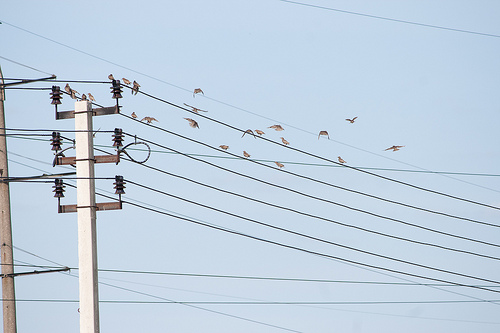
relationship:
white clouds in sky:
[399, 98, 495, 155] [0, 2, 499, 330]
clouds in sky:
[55, 0, 500, 278] [0, 2, 499, 330]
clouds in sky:
[58, 16, 498, 327] [203, 20, 445, 109]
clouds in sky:
[55, 0, 500, 278] [147, 12, 276, 96]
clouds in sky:
[55, 0, 500, 278] [124, 0, 499, 165]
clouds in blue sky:
[55, 0, 500, 278] [80, 1, 497, 132]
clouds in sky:
[55, 0, 500, 278] [4, 1, 499, 281]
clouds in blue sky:
[55, 0, 500, 278] [15, 5, 500, 158]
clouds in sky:
[55, 0, 500, 278] [212, 27, 433, 124]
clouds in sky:
[55, 0, 500, 278] [12, 11, 475, 331]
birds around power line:
[316, 114, 408, 168] [118, 92, 310, 149]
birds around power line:
[231, 122, 287, 165] [128, 199, 173, 222]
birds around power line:
[121, 75, 208, 130] [330, 166, 496, 210]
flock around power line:
[56, 72, 415, 180] [24, 31, 186, 93]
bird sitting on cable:
[278, 136, 288, 146] [0, 22, 500, 306]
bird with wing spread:
[386, 142, 403, 152] [382, 143, 404, 151]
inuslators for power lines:
[110, 75, 125, 202] [215, 109, 447, 264]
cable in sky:
[0, 22, 500, 306] [0, 2, 499, 330]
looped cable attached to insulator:
[122, 135, 148, 160] [106, 119, 127, 148]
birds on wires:
[51, 72, 411, 169] [0, 73, 499, 303]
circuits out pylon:
[46, 83, 67, 198] [67, 97, 101, 330]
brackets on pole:
[97, 63, 144, 231] [69, 88, 111, 330]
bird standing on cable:
[218, 141, 230, 152] [0, 22, 500, 306]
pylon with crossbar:
[67, 97, 101, 330] [42, 64, 129, 238]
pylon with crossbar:
[67, 97, 101, 330] [48, 83, 124, 118]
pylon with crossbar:
[67, 97, 101, 330] [45, 174, 126, 212]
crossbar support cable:
[42, 64, 129, 238] [11, 122, 495, 237]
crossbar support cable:
[45, 174, 126, 212] [16, 172, 498, 298]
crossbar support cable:
[48, 83, 124, 118] [4, 70, 497, 217]